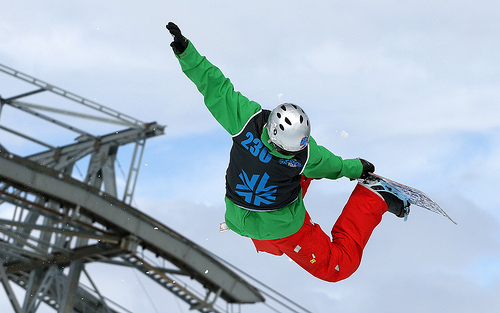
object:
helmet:
[267, 102, 311, 156]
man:
[164, 22, 409, 282]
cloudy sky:
[0, 0, 499, 313]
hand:
[352, 157, 373, 175]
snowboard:
[363, 171, 460, 225]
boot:
[364, 178, 410, 219]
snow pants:
[251, 183, 389, 283]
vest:
[227, 110, 309, 212]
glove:
[165, 22, 192, 56]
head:
[267, 102, 312, 155]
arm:
[318, 147, 355, 178]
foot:
[363, 178, 411, 218]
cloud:
[0, 0, 497, 313]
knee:
[315, 256, 357, 282]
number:
[241, 132, 272, 163]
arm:
[179, 56, 231, 99]